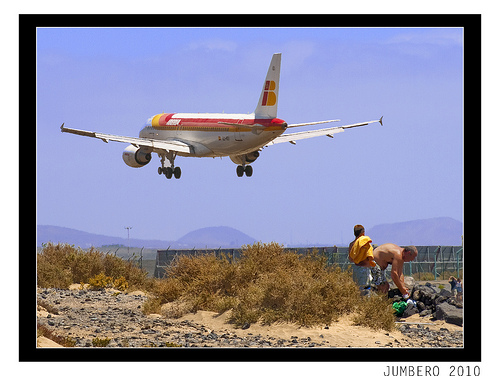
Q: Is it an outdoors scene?
A: Yes, it is outdoors.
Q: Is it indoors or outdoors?
A: It is outdoors.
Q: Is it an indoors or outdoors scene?
A: It is outdoors.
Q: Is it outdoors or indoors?
A: It is outdoors.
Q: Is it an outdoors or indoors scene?
A: It is outdoors.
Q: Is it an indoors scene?
A: No, it is outdoors.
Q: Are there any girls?
A: No, there are no girls.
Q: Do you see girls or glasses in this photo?
A: No, there are no girls or glasses.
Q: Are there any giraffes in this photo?
A: No, there are no giraffes.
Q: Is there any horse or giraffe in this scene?
A: No, there are no giraffes or horses.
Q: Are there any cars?
A: No, there are no cars.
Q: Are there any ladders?
A: No, there are no ladders.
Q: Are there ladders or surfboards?
A: No, there are no ladders or surfboards.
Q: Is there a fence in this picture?
A: Yes, there is a fence.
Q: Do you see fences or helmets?
A: Yes, there is a fence.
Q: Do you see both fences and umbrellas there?
A: No, there is a fence but no umbrellas.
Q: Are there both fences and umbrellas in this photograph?
A: No, there is a fence but no umbrellas.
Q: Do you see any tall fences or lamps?
A: Yes, there is a tall fence.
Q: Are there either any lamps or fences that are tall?
A: Yes, the fence is tall.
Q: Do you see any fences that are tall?
A: Yes, there is a tall fence.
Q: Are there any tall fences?
A: Yes, there is a tall fence.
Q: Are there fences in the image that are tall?
A: Yes, there is a fence that is tall.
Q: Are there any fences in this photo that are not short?
A: Yes, there is a tall fence.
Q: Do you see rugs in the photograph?
A: No, there are no rugs.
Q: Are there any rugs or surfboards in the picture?
A: No, there are no rugs or surfboards.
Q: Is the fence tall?
A: Yes, the fence is tall.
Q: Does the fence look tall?
A: Yes, the fence is tall.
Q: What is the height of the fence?
A: The fence is tall.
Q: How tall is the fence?
A: The fence is tall.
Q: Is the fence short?
A: No, the fence is tall.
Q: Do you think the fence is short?
A: No, the fence is tall.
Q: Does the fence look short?
A: No, the fence is tall.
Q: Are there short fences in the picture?
A: No, there is a fence but it is tall.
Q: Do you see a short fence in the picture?
A: No, there is a fence but it is tall.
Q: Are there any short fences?
A: No, there is a fence but it is tall.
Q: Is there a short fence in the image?
A: No, there is a fence but it is tall.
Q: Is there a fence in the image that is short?
A: No, there is a fence but it is tall.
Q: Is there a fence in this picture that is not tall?
A: No, there is a fence but it is tall.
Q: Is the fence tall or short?
A: The fence is tall.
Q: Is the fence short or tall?
A: The fence is tall.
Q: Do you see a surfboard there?
A: No, there are no surfboards.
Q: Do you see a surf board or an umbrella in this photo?
A: No, there are no surfboards or umbrellas.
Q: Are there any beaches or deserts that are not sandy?
A: No, there is a beach but it is sandy.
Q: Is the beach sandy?
A: Yes, the beach is sandy.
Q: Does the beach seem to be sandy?
A: Yes, the beach is sandy.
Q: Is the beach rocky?
A: No, the beach is sandy.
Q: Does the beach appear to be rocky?
A: No, the beach is sandy.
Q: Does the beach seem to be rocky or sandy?
A: The beach is sandy.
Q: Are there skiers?
A: No, there are no skiers.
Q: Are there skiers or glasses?
A: No, there are no skiers or glasses.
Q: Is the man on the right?
A: Yes, the man is on the right of the image.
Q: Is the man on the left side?
A: No, the man is on the right of the image.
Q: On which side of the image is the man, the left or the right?
A: The man is on the right of the image.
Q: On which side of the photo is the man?
A: The man is on the right of the image.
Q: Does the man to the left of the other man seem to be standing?
A: Yes, the man is standing.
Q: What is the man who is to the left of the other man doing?
A: The man is standing.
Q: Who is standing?
A: The man is standing.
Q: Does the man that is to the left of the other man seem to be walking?
A: No, the man is standing.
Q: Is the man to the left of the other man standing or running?
A: The man is standing.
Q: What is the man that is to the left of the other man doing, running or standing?
A: The man is standing.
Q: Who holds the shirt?
A: The man holds the shirt.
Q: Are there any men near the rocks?
A: Yes, there is a man near the rocks.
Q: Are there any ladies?
A: No, there are no ladies.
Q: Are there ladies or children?
A: No, there are no ladies or children.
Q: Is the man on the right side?
A: Yes, the man is on the right of the image.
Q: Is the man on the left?
A: No, the man is on the right of the image.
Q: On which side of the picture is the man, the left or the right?
A: The man is on the right of the image.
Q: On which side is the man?
A: The man is on the right of the image.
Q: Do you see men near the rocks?
A: Yes, there is a man near the rocks.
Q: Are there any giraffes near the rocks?
A: No, there is a man near the rocks.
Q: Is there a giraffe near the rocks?
A: No, there is a man near the rocks.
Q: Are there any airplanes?
A: Yes, there is an airplane.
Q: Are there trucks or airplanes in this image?
A: Yes, there is an airplane.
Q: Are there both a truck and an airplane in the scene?
A: No, there is an airplane but no trucks.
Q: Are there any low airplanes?
A: Yes, there is a low airplane.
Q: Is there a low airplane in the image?
A: Yes, there is a low airplane.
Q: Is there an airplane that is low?
A: Yes, there is an airplane that is low.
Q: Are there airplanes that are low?
A: Yes, there is an airplane that is low.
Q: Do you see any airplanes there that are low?
A: Yes, there is an airplane that is low.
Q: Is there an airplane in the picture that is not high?
A: Yes, there is a low airplane.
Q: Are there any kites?
A: No, there are no kites.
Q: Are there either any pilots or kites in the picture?
A: No, there are no kites or pilots.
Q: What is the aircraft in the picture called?
A: The aircraft is an airplane.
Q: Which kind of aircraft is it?
A: The aircraft is an airplane.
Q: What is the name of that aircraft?
A: This is an airplane.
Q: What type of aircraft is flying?
A: The aircraft is an airplane.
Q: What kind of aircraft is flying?
A: The aircraft is an airplane.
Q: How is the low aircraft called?
A: The aircraft is an airplane.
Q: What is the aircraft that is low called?
A: The aircraft is an airplane.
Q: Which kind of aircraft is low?
A: The aircraft is an airplane.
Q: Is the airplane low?
A: Yes, the airplane is low.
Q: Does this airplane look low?
A: Yes, the airplane is low.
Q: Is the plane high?
A: No, the plane is low.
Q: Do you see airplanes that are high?
A: No, there is an airplane but it is low.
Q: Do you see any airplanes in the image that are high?
A: No, there is an airplane but it is low.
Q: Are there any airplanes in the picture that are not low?
A: No, there is an airplane but it is low.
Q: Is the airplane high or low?
A: The airplane is low.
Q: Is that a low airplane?
A: Yes, that is a low airplane.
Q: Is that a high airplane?
A: No, that is a low airplane.